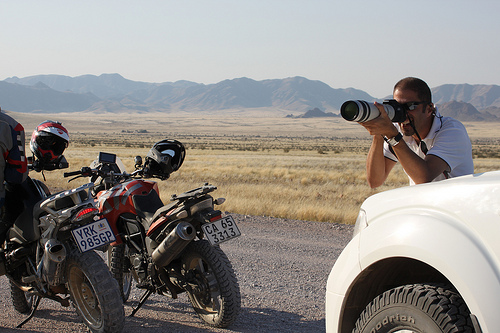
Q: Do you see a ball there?
A: No, there are no balls.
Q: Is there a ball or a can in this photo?
A: No, there are no balls or cans.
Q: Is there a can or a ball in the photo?
A: No, there are no balls or cans.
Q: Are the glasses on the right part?
A: Yes, the glasses are on the right of the image.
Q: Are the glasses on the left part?
A: No, the glasses are on the right of the image.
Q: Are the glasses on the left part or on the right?
A: The glasses are on the right of the image.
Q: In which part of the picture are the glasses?
A: The glasses are on the right of the image.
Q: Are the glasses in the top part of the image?
A: Yes, the glasses are in the top of the image.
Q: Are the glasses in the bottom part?
A: No, the glasses are in the top of the image.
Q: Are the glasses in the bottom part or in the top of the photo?
A: The glasses are in the top of the image.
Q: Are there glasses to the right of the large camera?
A: Yes, there are glasses to the right of the camera.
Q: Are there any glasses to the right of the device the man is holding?
A: Yes, there are glasses to the right of the camera.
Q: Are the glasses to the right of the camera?
A: Yes, the glasses are to the right of the camera.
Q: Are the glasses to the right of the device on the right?
A: Yes, the glasses are to the right of the camera.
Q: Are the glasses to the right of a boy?
A: No, the glasses are to the right of the camera.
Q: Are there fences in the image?
A: No, there are no fences.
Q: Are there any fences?
A: No, there are no fences.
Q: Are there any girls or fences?
A: No, there are no fences or girls.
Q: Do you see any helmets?
A: Yes, there is a helmet.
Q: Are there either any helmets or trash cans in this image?
A: Yes, there is a helmet.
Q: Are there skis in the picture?
A: No, there are no skis.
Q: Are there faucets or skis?
A: No, there are no skis or faucets.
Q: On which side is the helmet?
A: The helmet is on the left of the image.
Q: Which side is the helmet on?
A: The helmet is on the left of the image.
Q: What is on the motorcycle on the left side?
A: The helmet is on the motorbike.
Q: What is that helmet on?
A: The helmet is on the motorcycle.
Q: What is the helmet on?
A: The helmet is on the motorcycle.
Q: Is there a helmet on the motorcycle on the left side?
A: Yes, there is a helmet on the motorcycle.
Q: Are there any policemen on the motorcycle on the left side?
A: No, there is a helmet on the motorcycle.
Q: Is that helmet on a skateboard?
A: No, the helmet is on the motorbike.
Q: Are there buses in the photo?
A: No, there are no buses.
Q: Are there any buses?
A: No, there are no buses.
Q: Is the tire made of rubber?
A: Yes, the tire is made of rubber.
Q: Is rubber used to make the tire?
A: Yes, the tire is made of rubber.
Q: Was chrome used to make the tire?
A: No, the tire is made of rubber.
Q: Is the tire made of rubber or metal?
A: The tire is made of rubber.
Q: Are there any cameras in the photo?
A: Yes, there is a camera.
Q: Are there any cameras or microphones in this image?
A: Yes, there is a camera.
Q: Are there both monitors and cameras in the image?
A: No, there is a camera but no monitors.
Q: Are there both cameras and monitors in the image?
A: No, there is a camera but no monitors.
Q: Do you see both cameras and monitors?
A: No, there is a camera but no monitors.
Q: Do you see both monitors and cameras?
A: No, there is a camera but no monitors.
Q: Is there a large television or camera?
A: Yes, there is a large camera.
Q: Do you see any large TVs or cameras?
A: Yes, there is a large camera.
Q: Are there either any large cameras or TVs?
A: Yes, there is a large camera.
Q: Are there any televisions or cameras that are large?
A: Yes, the camera is large.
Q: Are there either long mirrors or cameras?
A: Yes, there is a long camera.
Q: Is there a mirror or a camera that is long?
A: Yes, the camera is long.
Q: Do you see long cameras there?
A: Yes, there is a long camera.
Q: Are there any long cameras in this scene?
A: Yes, there is a long camera.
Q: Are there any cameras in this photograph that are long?
A: Yes, there is a camera that is long.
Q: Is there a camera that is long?
A: Yes, there is a camera that is long.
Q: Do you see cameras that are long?
A: Yes, there is a camera that is long.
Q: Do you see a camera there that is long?
A: Yes, there is a camera that is long.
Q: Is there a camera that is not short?
A: Yes, there is a long camera.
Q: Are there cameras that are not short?
A: Yes, there is a long camera.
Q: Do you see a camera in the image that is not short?
A: Yes, there is a long camera.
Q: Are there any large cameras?
A: Yes, there is a large camera.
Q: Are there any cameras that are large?
A: Yes, there is a camera that is large.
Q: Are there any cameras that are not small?
A: Yes, there is a large camera.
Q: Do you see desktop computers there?
A: No, there are no desktop computers.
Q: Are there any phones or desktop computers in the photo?
A: No, there are no desktop computers or phones.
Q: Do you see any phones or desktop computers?
A: No, there are no desktop computers or phones.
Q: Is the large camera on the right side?
A: Yes, the camera is on the right of the image.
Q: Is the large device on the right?
A: Yes, the camera is on the right of the image.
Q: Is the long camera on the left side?
A: No, the camera is on the right of the image.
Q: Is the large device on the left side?
A: No, the camera is on the right of the image.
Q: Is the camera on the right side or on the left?
A: The camera is on the right of the image.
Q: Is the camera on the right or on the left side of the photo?
A: The camera is on the right of the image.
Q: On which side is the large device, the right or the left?
A: The camera is on the right of the image.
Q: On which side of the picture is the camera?
A: The camera is on the right of the image.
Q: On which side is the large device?
A: The camera is on the right of the image.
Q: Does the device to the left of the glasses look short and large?
A: No, the camera is large but long.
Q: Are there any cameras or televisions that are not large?
A: No, there is a camera but it is large.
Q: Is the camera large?
A: Yes, the camera is large.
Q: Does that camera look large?
A: Yes, the camera is large.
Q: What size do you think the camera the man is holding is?
A: The camera is large.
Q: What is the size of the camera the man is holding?
A: The camera is large.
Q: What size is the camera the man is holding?
A: The camera is large.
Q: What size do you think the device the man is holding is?
A: The camera is large.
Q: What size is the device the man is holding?
A: The camera is large.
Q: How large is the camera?
A: The camera is large.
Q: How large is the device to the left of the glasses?
A: The camera is large.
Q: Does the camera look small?
A: No, the camera is large.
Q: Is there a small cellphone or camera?
A: No, there is a camera but it is large.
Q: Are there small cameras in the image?
A: No, there is a camera but it is large.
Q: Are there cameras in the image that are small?
A: No, there is a camera but it is large.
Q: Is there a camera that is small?
A: No, there is a camera but it is large.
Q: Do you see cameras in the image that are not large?
A: No, there is a camera but it is large.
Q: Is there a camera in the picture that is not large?
A: No, there is a camera but it is large.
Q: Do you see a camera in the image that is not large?
A: No, there is a camera but it is large.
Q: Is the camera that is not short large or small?
A: The camera is large.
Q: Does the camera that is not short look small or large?
A: The camera is large.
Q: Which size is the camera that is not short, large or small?
A: The camera is large.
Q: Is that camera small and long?
A: No, the camera is long but large.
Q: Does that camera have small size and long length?
A: No, the camera is long but large.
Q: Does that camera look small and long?
A: No, the camera is long but large.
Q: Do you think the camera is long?
A: Yes, the camera is long.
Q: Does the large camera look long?
A: Yes, the camera is long.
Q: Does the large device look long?
A: Yes, the camera is long.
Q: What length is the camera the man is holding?
A: The camera is long.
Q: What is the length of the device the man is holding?
A: The camera is long.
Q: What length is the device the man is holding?
A: The camera is long.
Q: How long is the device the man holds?
A: The camera is long.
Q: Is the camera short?
A: No, the camera is long.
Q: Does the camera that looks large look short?
A: No, the camera is long.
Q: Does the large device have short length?
A: No, the camera is long.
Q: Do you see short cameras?
A: No, there is a camera but it is long.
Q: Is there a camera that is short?
A: No, there is a camera but it is long.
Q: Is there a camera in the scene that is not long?
A: No, there is a camera but it is long.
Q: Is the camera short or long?
A: The camera is long.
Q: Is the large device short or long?
A: The camera is long.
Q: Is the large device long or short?
A: The camera is long.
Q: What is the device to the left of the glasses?
A: The device is a camera.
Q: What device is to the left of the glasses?
A: The device is a camera.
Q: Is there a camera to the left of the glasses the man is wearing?
A: Yes, there is a camera to the left of the glasses.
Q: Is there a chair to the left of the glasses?
A: No, there is a camera to the left of the glasses.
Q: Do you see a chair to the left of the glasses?
A: No, there is a camera to the left of the glasses.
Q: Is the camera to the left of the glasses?
A: Yes, the camera is to the left of the glasses.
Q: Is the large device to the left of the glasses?
A: Yes, the camera is to the left of the glasses.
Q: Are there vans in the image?
A: No, there are no vans.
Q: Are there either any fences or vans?
A: No, there are no vans or fences.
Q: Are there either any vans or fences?
A: No, there are no vans or fences.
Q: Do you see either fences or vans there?
A: No, there are no vans or fences.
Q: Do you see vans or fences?
A: No, there are no vans or fences.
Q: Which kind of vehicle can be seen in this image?
A: The vehicle is a car.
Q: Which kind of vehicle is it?
A: The vehicle is a car.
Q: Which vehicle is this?
A: This is a car.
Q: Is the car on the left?
A: No, the car is on the right of the image.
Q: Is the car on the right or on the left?
A: The car is on the right of the image.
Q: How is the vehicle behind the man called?
A: The vehicle is a car.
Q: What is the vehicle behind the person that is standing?
A: The vehicle is a car.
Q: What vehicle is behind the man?
A: The vehicle is a car.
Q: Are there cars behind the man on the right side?
A: Yes, there is a car behind the man.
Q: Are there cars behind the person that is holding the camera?
A: Yes, there is a car behind the man.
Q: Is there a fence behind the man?
A: No, there is a car behind the man.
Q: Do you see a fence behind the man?
A: No, there is a car behind the man.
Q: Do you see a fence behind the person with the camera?
A: No, there is a car behind the man.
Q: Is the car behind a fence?
A: No, the car is behind a man.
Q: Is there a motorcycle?
A: Yes, there is a motorcycle.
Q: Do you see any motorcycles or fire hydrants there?
A: Yes, there is a motorcycle.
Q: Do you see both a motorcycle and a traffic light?
A: No, there is a motorcycle but no traffic lights.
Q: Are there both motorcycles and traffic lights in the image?
A: No, there is a motorcycle but no traffic lights.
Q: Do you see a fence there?
A: No, there are no fences.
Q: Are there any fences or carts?
A: No, there are no fences or carts.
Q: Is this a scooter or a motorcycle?
A: This is a motorcycle.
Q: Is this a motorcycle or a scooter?
A: This is a motorcycle.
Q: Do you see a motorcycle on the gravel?
A: Yes, there is a motorcycle on the gravel.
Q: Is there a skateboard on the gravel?
A: No, there is a motorcycle on the gravel.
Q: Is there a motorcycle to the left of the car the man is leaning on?
A: Yes, there is a motorcycle to the left of the car.